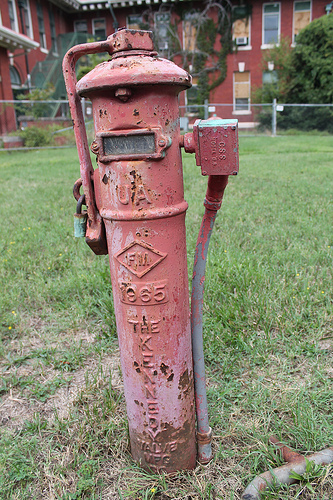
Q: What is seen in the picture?
A: Pump.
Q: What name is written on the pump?
A: The Kennedy.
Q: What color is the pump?
A: Red.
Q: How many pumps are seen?
A: One.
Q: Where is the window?
A: In the wall.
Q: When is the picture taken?
A: Daytime.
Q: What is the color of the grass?
A: Green.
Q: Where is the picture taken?
A: In a backyard.